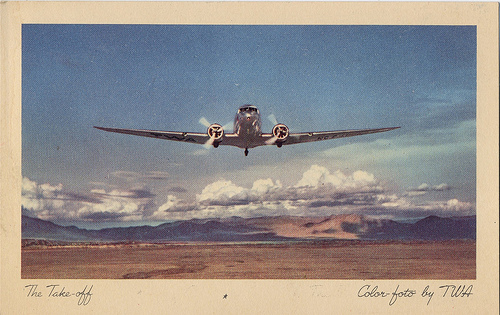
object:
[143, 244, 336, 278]
desert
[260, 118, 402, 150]
wing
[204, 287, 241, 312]
star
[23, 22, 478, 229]
sky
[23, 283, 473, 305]
writing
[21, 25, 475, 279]
picture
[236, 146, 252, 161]
wheel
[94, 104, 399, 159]
plane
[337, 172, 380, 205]
cloud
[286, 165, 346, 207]
cloud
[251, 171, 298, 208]
cloud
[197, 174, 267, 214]
cloud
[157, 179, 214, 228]
cloud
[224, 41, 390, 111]
sky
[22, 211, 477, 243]
mountains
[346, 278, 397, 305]
word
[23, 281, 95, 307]
photo name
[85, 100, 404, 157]
airplane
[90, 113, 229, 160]
wing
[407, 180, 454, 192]
cloud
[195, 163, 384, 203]
cloud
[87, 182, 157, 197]
cloud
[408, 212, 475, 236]
mountain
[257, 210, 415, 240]
mountain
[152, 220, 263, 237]
mountain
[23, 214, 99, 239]
mountain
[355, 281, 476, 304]
name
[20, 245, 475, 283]
land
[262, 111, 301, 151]
propeller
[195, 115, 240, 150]
propeller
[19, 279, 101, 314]
writing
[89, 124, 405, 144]
wings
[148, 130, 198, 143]
twa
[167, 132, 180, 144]
'w'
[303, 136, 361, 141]
writing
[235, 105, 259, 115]
window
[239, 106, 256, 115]
windshield